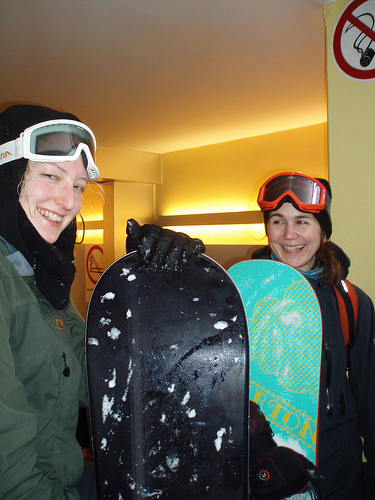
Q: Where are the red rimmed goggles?
A: On the woman's head.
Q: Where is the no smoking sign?
A: On the wall.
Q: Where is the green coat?
A: On the woman to the left.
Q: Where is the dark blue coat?
A: On the woman to the right.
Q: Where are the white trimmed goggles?
A: On the woman's head.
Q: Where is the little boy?
A: There isn't a little boy.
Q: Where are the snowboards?
A: In front of the women.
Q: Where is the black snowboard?
A: In front of the blue snowboard.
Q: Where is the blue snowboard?
A: Next to the black one.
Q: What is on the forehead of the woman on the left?
A: Goggles.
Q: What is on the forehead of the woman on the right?
A: Goggles.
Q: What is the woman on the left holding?
A: Snowboard.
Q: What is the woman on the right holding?
A: Snowboard.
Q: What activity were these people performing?
A: Snowboarding.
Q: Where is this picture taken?
A: A ski resort.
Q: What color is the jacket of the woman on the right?
A: Blue.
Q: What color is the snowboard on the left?
A: Black.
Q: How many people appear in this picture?
A: Two.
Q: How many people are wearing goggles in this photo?
A: Two.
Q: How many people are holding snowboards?
A: Two.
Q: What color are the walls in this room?
A: Yellow.